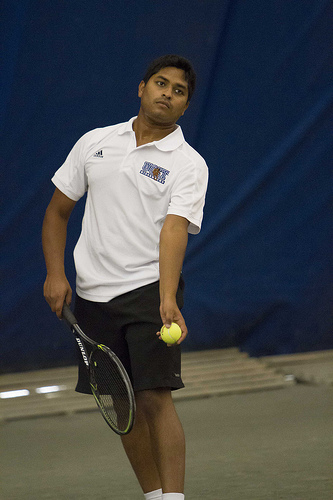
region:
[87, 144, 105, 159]
shirt manufacturer logo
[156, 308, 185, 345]
holdin the tennis ball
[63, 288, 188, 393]
man wears black shorts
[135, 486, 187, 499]
white ankle socks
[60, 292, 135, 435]
black with green accents racquet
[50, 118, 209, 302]
white polo shirt with short sleeves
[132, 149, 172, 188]
tournament name on the shirt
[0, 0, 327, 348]
a blue tarp is over the back wall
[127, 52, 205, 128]
man has black hair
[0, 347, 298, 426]
slatted wood pallets on the ground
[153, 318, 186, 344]
a yellow tennis ball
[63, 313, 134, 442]
a black tennis racket with green accent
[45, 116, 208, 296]
a white Adidas tennis shirt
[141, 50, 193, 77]
thick dark brown hair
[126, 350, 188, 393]
left leg of black tennis shorts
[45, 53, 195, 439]
a man getting ready to serve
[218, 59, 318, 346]
a dark blue drop cloth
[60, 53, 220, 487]
a young man playing tennis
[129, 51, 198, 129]
a young dark complected man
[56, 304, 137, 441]
a Dunlap tennis racket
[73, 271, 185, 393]
Loose dark grey shorts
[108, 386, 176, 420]
Person's pair of knees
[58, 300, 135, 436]
Grey tennis racket with bright green accents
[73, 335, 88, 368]
Logo on a tennis racket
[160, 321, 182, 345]
Bright green tennis ball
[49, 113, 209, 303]
White polo shirt with logos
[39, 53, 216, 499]
Male tennis player on tennis court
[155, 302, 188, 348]
Hand holding a tennis ball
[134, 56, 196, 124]
Head of a man with short, dark hair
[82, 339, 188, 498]
Person's hairy legs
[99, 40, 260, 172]
Man with dark hair.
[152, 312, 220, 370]
Yellow tennis ball.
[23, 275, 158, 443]
Man with a tennis racket.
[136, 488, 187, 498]
White socks on the man.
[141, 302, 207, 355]
Hand holding the tennis ball.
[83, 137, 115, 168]
Adidas logo.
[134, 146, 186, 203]
Name on the man's white polo.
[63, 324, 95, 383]
Brand on the racket.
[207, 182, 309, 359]
Blue backdrop in the background.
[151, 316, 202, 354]
Yellow ball.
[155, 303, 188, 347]
the man is holding a ball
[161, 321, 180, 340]
the ball is green in color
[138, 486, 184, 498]
the man is wearing socks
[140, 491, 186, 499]
the socks are white in color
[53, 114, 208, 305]
the man is wearing a short sleeve shirt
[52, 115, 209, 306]
the shirt is white in color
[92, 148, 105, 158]
a logo is on the shirt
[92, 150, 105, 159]
the logo is black in color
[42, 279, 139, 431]
the man is holding a racquet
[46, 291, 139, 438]
the racquet is black in color